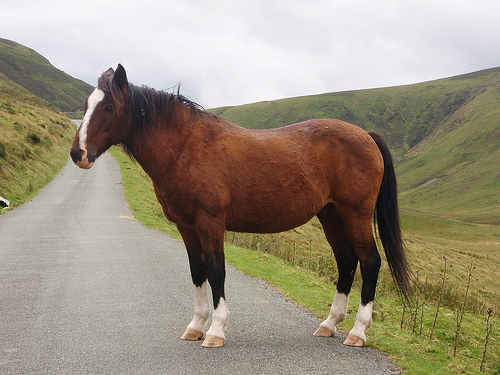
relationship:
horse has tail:
[80, 65, 392, 345] [368, 131, 417, 311]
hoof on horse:
[203, 337, 223, 348] [80, 65, 392, 345]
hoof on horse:
[183, 328, 201, 339] [80, 65, 392, 345]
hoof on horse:
[343, 335, 364, 353] [80, 65, 392, 345]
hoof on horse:
[315, 329, 333, 337] [80, 65, 392, 345]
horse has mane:
[80, 65, 392, 345] [111, 70, 207, 145]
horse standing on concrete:
[80, 65, 392, 345] [6, 116, 395, 375]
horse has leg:
[80, 65, 392, 345] [193, 210, 231, 349]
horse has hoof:
[80, 65, 392, 345] [203, 337, 223, 348]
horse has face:
[80, 65, 392, 345] [70, 72, 123, 162]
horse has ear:
[80, 65, 392, 345] [115, 66, 128, 90]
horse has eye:
[80, 65, 392, 345] [102, 107, 113, 113]